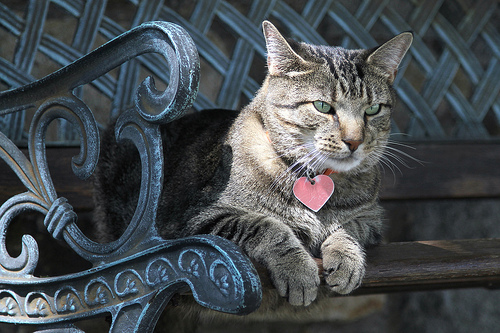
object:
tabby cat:
[90, 17, 432, 333]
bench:
[1, 0, 498, 332]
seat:
[0, 137, 499, 297]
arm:
[0, 15, 268, 332]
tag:
[290, 173, 337, 213]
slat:
[171, 235, 500, 295]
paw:
[266, 244, 321, 307]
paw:
[318, 231, 369, 296]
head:
[247, 18, 416, 184]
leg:
[173, 203, 323, 308]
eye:
[310, 99, 336, 115]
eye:
[363, 102, 385, 117]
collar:
[250, 108, 342, 182]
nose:
[336, 116, 367, 151]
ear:
[259, 16, 312, 76]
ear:
[363, 30, 415, 85]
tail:
[103, 295, 203, 333]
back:
[1, 0, 500, 148]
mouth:
[318, 147, 365, 163]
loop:
[305, 165, 318, 183]